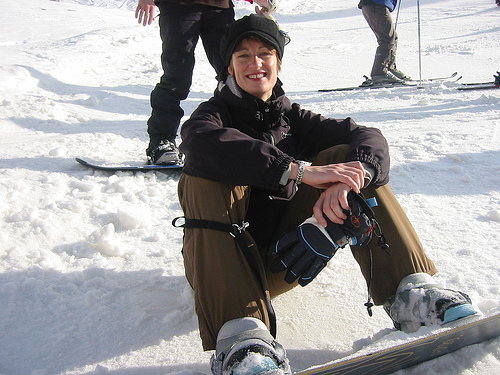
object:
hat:
[204, 9, 294, 59]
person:
[341, 2, 422, 88]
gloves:
[264, 181, 378, 288]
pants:
[139, 1, 264, 162]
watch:
[282, 152, 313, 195]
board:
[261, 289, 499, 374]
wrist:
[290, 161, 306, 186]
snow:
[1, 176, 178, 371]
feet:
[383, 276, 485, 333]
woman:
[167, 14, 482, 372]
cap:
[220, 14, 288, 57]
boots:
[380, 272, 486, 337]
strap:
[158, 199, 299, 315]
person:
[135, 0, 276, 172]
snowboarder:
[316, 74, 500, 100]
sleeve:
[181, 108, 296, 190]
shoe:
[382, 271, 478, 329]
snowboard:
[72, 151, 227, 181]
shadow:
[0, 142, 152, 185]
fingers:
[336, 172, 359, 195]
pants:
[172, 168, 482, 354]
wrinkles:
[386, 229, 442, 275]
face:
[233, 48, 275, 90]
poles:
[400, 1, 429, 85]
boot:
[206, 312, 298, 373]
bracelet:
[290, 157, 308, 192]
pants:
[336, 2, 416, 98]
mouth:
[240, 71, 271, 85]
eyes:
[237, 49, 250, 61]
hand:
[280, 152, 370, 194]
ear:
[225, 57, 235, 78]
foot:
[206, 315, 294, 374]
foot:
[382, 269, 492, 333]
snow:
[235, 351, 271, 371]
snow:
[397, 285, 451, 320]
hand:
[306, 155, 366, 194]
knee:
[175, 176, 226, 197]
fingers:
[312, 201, 336, 228]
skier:
[315, 0, 499, 99]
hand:
[307, 181, 358, 229]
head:
[210, 11, 294, 96]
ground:
[6, 7, 499, 373]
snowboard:
[295, 314, 499, 373]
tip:
[441, 300, 476, 326]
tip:
[234, 354, 280, 372]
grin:
[241, 69, 272, 84]